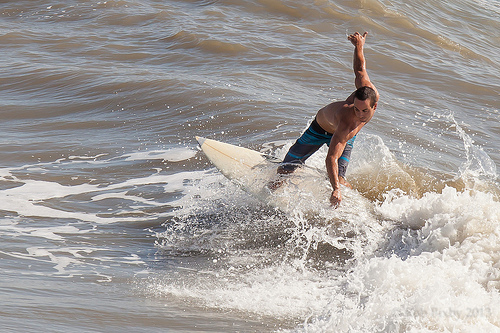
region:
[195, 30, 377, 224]
man on a surf board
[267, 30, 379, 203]
the man is white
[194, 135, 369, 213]
the surfboard is white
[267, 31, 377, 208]
man is bending over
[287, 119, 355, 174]
shorts are blue and black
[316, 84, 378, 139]
man has no shirt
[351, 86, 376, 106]
the hair is brown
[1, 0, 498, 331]
the water is brown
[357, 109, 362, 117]
nose of a man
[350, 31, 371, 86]
arm is sticking up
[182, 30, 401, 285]
man is surfing in the ocean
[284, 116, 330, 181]
man is wearing blue and black shorts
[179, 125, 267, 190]
white surfboard coming out of the water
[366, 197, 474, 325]
surfboard splashing in the water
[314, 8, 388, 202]
picture shows body at an odd angle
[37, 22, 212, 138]
ocean water is a dirty grey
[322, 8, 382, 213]
man's arms are straight out on the sides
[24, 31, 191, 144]
vast body of water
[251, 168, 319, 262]
water is splashing up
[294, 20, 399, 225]
man is in the ocean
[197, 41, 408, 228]
man riding on surf board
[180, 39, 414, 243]
man surfing on wave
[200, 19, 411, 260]
man surfing on board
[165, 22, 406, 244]
man riding short board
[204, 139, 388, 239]
white short board in wave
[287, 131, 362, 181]
blue board shorts on man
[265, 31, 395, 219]
man surfing with shirt off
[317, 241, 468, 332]
white water from wave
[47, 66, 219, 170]
waves in the ocean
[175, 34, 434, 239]
person surfing ocean waves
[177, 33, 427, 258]
male person surfing ocean waves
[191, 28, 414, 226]
person surfing some ocean waves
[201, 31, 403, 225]
person surfing nice ocean waves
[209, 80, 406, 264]
person surfing awesome ocean waves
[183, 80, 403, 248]
person surfing great ocean waves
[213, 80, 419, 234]
person surfing beautiful ocean waves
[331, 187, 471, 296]
some really nice ocean waves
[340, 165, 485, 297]
some rough ocean waves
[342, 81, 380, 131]
person with dark hair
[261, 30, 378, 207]
man twisting for his balance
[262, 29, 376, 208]
man surfing in warm water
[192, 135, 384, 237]
pointed surfboard ridden by a man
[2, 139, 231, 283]
foam on the surface of the water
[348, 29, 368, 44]
left hand of the surfer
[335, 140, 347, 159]
right bicep of the surfer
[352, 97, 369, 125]
shaded face of the surfer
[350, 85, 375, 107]
close cut hair of the surfer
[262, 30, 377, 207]
person twisting for balance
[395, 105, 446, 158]
droplets of water in the air